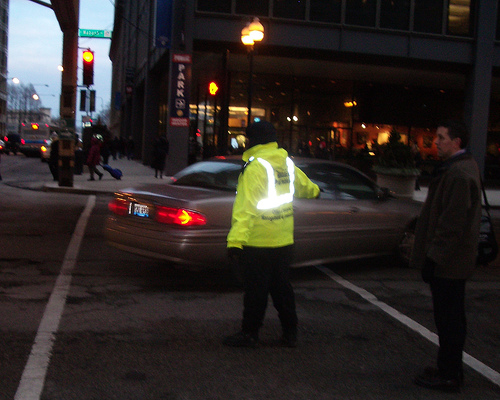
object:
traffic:
[2, 119, 57, 160]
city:
[0, 0, 500, 400]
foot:
[232, 315, 271, 343]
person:
[152, 132, 172, 179]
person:
[124, 132, 134, 158]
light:
[233, 17, 268, 51]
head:
[430, 116, 466, 158]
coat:
[400, 151, 490, 287]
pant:
[241, 242, 303, 338]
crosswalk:
[13, 184, 498, 398]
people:
[98, 113, 118, 183]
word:
[177, 62, 187, 107]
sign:
[172, 50, 188, 127]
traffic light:
[78, 47, 95, 111]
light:
[156, 204, 206, 227]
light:
[105, 200, 128, 210]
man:
[221, 120, 324, 349]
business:
[61, 0, 500, 199]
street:
[0, 145, 500, 399]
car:
[103, 152, 426, 283]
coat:
[225, 141, 321, 257]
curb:
[387, 359, 484, 392]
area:
[0, 0, 500, 400]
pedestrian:
[415, 124, 485, 390]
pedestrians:
[78, 128, 104, 183]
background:
[0, 110, 477, 185]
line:
[11, 189, 101, 400]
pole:
[171, 51, 197, 138]